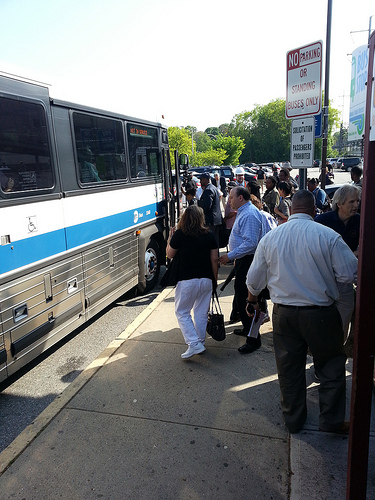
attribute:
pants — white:
[169, 278, 218, 362]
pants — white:
[173, 281, 216, 362]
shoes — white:
[178, 339, 206, 362]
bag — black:
[204, 300, 230, 340]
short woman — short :
[167, 209, 220, 363]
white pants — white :
[172, 274, 218, 360]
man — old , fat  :
[219, 184, 273, 356]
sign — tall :
[280, 39, 324, 173]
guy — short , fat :
[245, 190, 367, 433]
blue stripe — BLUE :
[83, 225, 101, 235]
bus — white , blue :
[5, 60, 177, 390]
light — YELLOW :
[62, 279, 85, 291]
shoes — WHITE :
[179, 341, 206, 360]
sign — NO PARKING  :
[274, 39, 331, 172]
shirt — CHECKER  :
[247, 216, 357, 317]